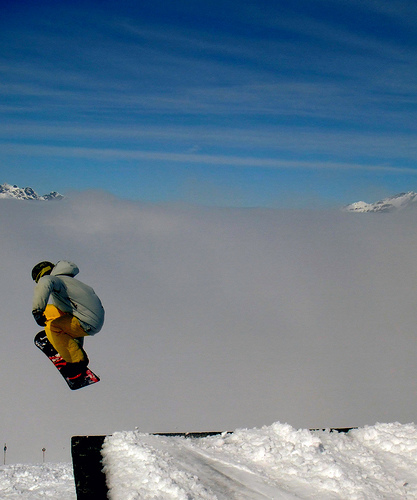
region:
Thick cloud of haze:
[10, 198, 387, 457]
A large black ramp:
[64, 432, 397, 495]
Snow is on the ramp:
[63, 423, 407, 496]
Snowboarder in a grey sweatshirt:
[18, 243, 112, 402]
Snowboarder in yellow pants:
[23, 255, 117, 386]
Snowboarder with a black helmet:
[23, 248, 134, 408]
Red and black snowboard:
[32, 326, 103, 393]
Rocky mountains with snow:
[7, 175, 413, 216]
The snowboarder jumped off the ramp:
[25, 255, 134, 409]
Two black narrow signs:
[2, 440, 50, 465]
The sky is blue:
[99, 47, 407, 179]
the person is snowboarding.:
[28, 257, 98, 391]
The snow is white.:
[149, 275, 336, 378]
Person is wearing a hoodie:
[48, 268, 110, 329]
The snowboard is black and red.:
[45, 328, 99, 391]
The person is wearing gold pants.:
[48, 315, 90, 354]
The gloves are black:
[27, 307, 48, 328]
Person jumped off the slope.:
[27, 251, 280, 472]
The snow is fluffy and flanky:
[247, 436, 368, 480]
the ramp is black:
[63, 417, 102, 498]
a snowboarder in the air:
[15, 251, 128, 398]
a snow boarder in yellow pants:
[13, 257, 132, 398]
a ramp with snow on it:
[50, 417, 343, 493]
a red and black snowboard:
[21, 320, 122, 402]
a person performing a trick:
[19, 254, 123, 404]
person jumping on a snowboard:
[22, 257, 126, 398]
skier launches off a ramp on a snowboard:
[19, 248, 220, 494]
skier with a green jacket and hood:
[12, 245, 132, 405]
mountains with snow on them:
[0, 186, 96, 215]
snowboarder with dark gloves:
[8, 244, 138, 416]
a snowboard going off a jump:
[28, 329, 104, 390]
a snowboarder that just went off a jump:
[19, 251, 110, 396]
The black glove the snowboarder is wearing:
[27, 309, 54, 328]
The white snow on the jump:
[97, 426, 416, 495]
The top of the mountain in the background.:
[336, 189, 415, 218]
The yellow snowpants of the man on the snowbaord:
[35, 302, 96, 360]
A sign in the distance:
[32, 443, 54, 462]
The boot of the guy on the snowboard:
[57, 357, 98, 378]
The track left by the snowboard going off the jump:
[166, 434, 294, 495]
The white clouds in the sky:
[3, 118, 416, 163]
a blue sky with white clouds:
[1, 3, 410, 170]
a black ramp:
[57, 411, 108, 497]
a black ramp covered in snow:
[59, 420, 415, 497]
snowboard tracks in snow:
[94, 432, 415, 495]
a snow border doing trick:
[16, 253, 133, 422]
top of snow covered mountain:
[0, 173, 85, 212]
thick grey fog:
[158, 207, 351, 416]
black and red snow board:
[29, 325, 110, 398]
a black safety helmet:
[28, 258, 68, 288]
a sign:
[36, 443, 53, 464]